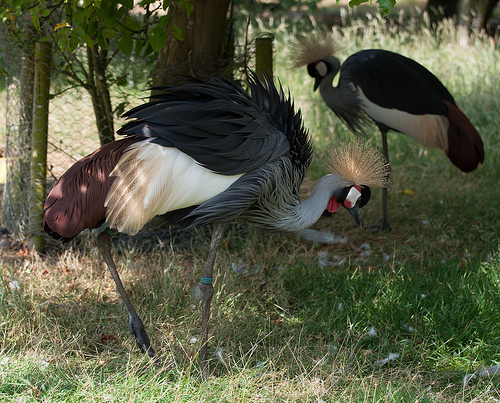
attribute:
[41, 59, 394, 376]
bird — right facing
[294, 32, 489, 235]
bird — left facing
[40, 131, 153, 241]
tail — red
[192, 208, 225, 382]
right leg — thin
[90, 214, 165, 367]
left leg — thin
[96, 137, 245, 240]
feathers — white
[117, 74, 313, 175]
feathers — black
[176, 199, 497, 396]
feathers — white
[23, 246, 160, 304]
spot — brown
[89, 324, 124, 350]
spot — red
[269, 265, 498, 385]
part — grass, green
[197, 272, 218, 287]
band — green, blue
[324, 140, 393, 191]
plume — white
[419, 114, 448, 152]
feathers — tan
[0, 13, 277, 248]
fence — chain link, mesh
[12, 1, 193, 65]
leaves — green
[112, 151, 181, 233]
feather — large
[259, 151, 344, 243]
feathers — gray